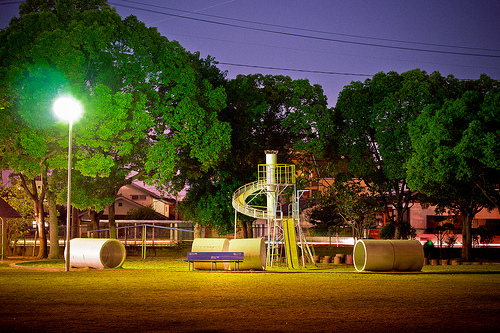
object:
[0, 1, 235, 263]
tall tree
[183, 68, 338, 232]
tree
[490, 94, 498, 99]
leaves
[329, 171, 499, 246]
building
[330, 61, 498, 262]
trees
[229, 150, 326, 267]
slide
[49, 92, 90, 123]
light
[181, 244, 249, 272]
bench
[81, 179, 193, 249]
house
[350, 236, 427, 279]
tube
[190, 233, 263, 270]
tube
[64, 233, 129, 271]
tube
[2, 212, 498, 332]
play area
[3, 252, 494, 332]
grass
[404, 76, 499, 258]
tree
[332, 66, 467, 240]
tree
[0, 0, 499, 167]
sky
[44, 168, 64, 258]
trunk